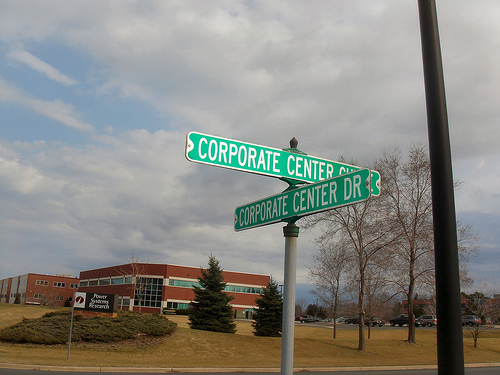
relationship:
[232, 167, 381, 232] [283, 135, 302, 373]
street sign on pole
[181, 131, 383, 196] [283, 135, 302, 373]
street sign on pole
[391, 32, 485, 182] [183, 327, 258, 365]
pole in ground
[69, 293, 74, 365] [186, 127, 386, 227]
pole holds sign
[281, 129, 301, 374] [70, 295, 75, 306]
pole holds sign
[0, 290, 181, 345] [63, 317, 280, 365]
bushes atop grass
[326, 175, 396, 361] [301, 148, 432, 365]
forest filled with trees